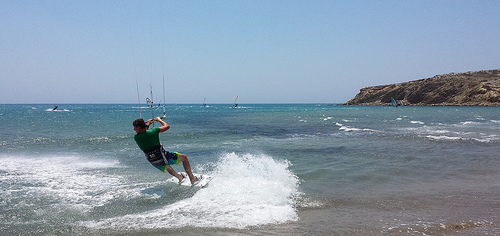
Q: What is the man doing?
A: Surfing.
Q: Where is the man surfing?
A: On the beach.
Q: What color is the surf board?
A: White.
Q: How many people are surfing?
A: One.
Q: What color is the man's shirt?
A: Green.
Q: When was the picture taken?
A: Daytime.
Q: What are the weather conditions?
A: Clear.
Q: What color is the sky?
A: Blue.